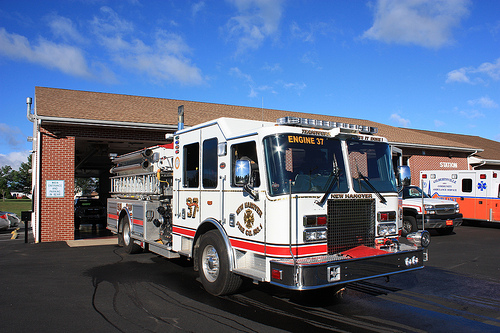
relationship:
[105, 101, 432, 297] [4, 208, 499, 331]
ambulance on road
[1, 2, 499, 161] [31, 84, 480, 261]
sky above building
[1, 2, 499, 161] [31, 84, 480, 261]
sky near building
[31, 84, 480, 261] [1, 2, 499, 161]
building near sky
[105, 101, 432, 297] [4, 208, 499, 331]
ambulance on top of road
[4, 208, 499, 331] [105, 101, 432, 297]
road below ambulance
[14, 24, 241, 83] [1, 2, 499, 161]
clouds in sky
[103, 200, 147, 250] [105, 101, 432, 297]
wheel of ambulance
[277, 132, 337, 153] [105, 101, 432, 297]
engine 37 on ambulance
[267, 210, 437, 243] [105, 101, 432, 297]
lights on ambulance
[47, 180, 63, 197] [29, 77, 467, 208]
poster on building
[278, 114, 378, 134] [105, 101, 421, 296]
sirens of engine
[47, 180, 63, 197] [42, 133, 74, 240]
poster on wall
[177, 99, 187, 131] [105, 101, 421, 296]
pipe of engine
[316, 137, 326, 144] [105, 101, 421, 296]
number of engine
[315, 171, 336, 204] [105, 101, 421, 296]
wipers of engine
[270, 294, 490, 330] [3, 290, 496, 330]
streaks on ground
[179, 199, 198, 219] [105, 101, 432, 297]
37 printed on side of ambulance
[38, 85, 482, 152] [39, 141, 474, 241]
roof on building